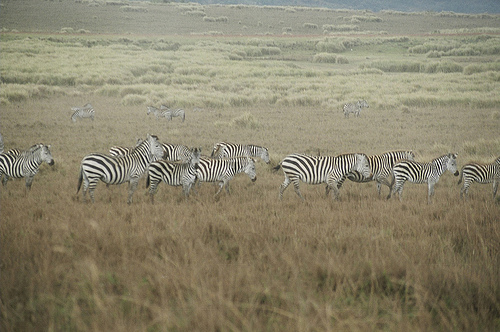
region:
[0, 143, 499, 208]
Zebras walking in a field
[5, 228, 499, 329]
Brown and green grass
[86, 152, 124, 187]
White and black stripes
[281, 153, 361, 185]
Stripes on a zebra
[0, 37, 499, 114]
Light green bushes on field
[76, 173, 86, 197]
Black tip of zebra's tail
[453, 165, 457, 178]
Black nose of zebra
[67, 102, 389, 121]
Zebra's standing in front of bushes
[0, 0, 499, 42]
Scattered bushes in field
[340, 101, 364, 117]
Zebra standing on a field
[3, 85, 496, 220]
a large herd of zebras are on the plain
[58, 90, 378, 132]
zebras are in the background near the tall grass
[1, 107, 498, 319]
the grass around the zebras is brown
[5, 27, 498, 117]
thickets of bushes are behind the zebras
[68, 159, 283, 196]
the tail tufts of the zebras are stiff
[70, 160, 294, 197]
the zebra's tail tufts have black hair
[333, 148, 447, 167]
the manes on the zebras are black and white stripes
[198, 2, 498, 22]
water is in the distance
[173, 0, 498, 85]
a river is behind the green thickets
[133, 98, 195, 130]
two zebras are standing alone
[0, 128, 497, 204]
a herd of zebras in a field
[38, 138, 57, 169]
a head of a zebra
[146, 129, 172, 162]
a head of a zebra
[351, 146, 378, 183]
a head of a zebra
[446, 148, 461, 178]
a head of a zebra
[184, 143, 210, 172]
a head of a zebra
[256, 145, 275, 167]
a head of a zebra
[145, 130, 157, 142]
the ear of a zebra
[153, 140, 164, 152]
the eye of a zebra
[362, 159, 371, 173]
the eye of a zebra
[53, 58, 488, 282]
zebras in a field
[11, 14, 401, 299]
zebras standing in a field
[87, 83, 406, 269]
zebras standing together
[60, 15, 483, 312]
a field with zebras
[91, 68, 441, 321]
a field with standing zebras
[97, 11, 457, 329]
a field of grass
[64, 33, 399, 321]
a field of tall grass with zebras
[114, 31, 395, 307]
zebras in a field of tall grass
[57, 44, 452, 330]
an area with zebras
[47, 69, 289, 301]
zebras in an area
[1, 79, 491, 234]
A heard of zebras standing in a field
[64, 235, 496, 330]
Tall brown grass in front of the zebras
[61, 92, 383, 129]
A small group of zebras behind the larger group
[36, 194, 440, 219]
Short brown grass grows by the zebras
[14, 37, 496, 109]
Tall green vegetation growing far behind the zebras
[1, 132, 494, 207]
The zebras are black and white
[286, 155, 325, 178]
Black stripes on a zebra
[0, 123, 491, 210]
None of the zebras are grazing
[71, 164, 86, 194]
The black drooping tail of a zebra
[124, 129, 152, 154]
A small mane on the zebra's back